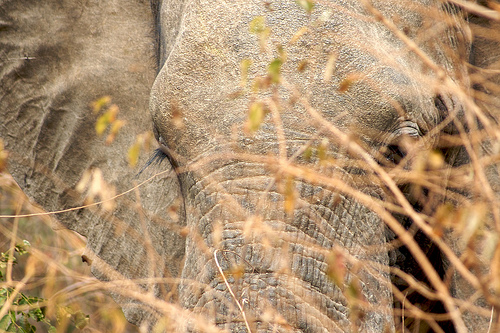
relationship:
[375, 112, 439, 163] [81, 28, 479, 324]
eye of elephant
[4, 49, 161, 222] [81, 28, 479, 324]
ear of elephant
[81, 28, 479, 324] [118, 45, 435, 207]
elephant has head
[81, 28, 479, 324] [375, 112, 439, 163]
elephant has eye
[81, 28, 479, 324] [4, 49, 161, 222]
elephant has ear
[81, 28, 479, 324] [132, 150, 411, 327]
elephant has trunk